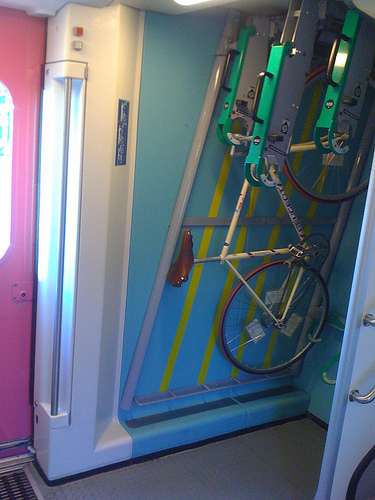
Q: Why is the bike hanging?
A: Storage.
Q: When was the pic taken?
A: During the day.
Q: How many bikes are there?
A: 1.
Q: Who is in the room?
A: No one.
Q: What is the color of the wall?
A: Blue.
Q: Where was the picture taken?
A: In a house.